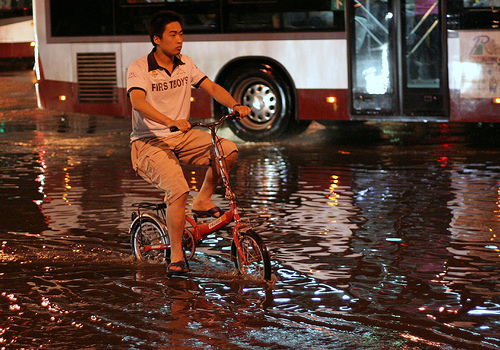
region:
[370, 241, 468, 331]
water on the ground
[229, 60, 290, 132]
black tire on the bus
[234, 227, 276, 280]
black tire on front of bike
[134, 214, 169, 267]
back tire on bike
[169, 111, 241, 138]
handlebars on the bike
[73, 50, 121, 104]
vent on back of bus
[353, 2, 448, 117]
doors on side of bus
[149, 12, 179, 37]
the boy's black hair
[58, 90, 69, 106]
light on bottom of bus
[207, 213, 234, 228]
brand name printed on bike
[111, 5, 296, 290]
man biking down flooded street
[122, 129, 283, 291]
red bicycle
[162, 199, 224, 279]
black flip flops man is wearing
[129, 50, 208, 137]
white shirt with black trim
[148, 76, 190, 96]
black lettering on white shirt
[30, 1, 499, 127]
red and white bus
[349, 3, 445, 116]
double doors on the bus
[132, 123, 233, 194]
khaki shorts worn by man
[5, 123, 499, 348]
flooded area of the street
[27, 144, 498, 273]
bus reflected in water's surface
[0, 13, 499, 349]
A man riding a bike on a flooded street.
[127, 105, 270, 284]
The bike frame is orange.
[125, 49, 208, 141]
A white shirt with a black collar.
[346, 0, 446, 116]
Black doors on the bus.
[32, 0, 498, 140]
A red and white bus behind the man.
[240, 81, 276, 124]
A silver hubcap on the bus tire.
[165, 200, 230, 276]
Feet in black sandals.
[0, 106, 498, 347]
Ripples on the surface of the water.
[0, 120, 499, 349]
Lights reflecting off the water surface.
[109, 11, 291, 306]
man driving a bike on the water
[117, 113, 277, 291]
the bike is color red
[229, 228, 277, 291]
front wheel of bike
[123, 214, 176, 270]
back wheel of bike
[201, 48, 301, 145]
back wheel of bus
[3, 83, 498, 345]
the road is flooded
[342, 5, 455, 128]
the door of a bus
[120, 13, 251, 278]
man wears a white shirt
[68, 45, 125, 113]
vents of a bus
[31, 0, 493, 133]
bus is white and red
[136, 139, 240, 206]
man wearing tan shorts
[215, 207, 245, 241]
man on small red bike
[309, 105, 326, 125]
red and white bus in back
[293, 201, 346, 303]
water has small ripples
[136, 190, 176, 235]
bike has rack in back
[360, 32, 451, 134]
dark back door on bus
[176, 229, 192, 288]
man in black sandals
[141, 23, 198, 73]
man has black hair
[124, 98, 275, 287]
The bike in the water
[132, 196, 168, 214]
The rack on the back of the bike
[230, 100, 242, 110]
The black band on the wrist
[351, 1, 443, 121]
The door on the bus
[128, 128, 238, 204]
The shorts on the man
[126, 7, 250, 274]
The man riding the bike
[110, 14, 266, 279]
man riding bike in water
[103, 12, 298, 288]
man riding bike in water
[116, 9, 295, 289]
man riding bike in water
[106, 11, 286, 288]
man riding bike in water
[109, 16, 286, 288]
man riding bike in water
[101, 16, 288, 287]
man riding bike in water